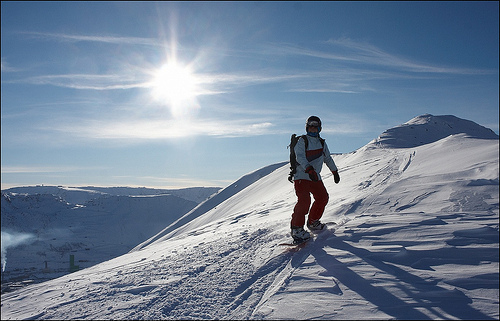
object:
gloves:
[303, 166, 319, 181]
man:
[290, 114, 340, 239]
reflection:
[290, 224, 500, 320]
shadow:
[290, 228, 500, 319]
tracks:
[364, 152, 414, 187]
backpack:
[286, 132, 327, 183]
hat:
[306, 115, 322, 125]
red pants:
[290, 178, 328, 226]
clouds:
[286, 88, 359, 94]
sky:
[1, 0, 500, 190]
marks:
[287, 285, 344, 294]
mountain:
[0, 185, 222, 294]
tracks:
[130, 231, 265, 320]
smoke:
[0, 31, 500, 137]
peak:
[357, 113, 499, 150]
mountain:
[0, 114, 498, 319]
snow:
[0, 114, 500, 319]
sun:
[139, 56, 212, 124]